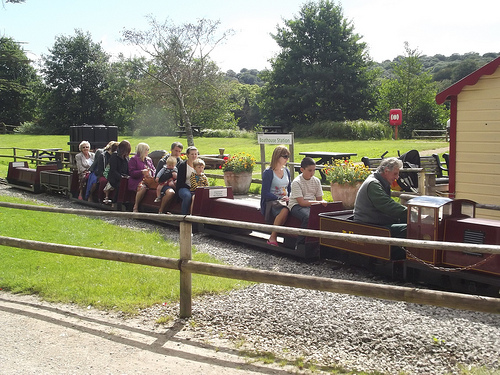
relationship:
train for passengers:
[8, 126, 499, 299] [77, 140, 426, 245]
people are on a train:
[78, 139, 422, 247] [8, 126, 499, 299]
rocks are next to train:
[2, 183, 498, 375] [8, 126, 499, 299]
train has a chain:
[8, 126, 499, 299] [400, 247, 498, 273]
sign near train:
[258, 134, 292, 149] [8, 126, 499, 299]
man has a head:
[353, 158, 420, 223] [380, 158, 401, 183]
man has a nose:
[353, 158, 420, 223] [395, 174, 400, 181]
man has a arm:
[353, 158, 420, 223] [369, 184, 420, 223]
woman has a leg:
[265, 149, 292, 247] [268, 204, 288, 249]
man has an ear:
[353, 158, 420, 223] [384, 166, 391, 175]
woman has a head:
[265, 149, 292, 247] [272, 145, 291, 169]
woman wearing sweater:
[265, 149, 292, 247] [262, 169, 295, 209]